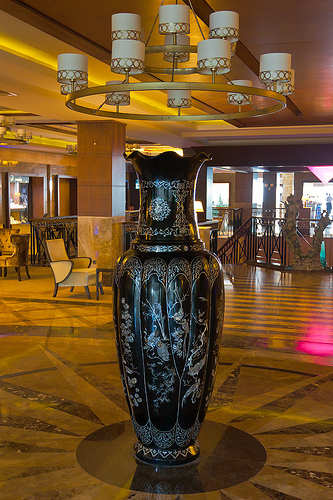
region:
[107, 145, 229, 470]
a large black vase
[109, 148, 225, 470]
the vase has flowers on it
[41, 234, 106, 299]
a cream colored chair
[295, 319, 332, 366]
a pink reflection on the floor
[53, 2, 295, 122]
a large golden chandelier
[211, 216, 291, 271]
the railing is black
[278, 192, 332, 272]
a sculpture in front of the railing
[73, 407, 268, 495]
a brown circle on the floor around the vase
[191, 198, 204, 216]
the lamp is lit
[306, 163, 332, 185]
a pink triangular light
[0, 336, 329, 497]
Flooring with a star design.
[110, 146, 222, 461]
A tall decorative vase.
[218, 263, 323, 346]
Brown striped flooring.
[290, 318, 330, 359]
Pink light reflecting off of the floor.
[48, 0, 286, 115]
A chandelier hanging from the ceiling.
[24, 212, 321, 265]
Black metal railing.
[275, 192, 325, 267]
Statue shaped like a tree trunk.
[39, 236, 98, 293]
Tan chair with a brown frame.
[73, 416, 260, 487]
A brown circle on the flooring.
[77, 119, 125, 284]
A brown and tan beam.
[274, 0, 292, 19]
part of a ceiling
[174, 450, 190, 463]
edge of a vase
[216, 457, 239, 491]
part of a surface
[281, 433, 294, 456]
part of a surface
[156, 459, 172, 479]
base of a vase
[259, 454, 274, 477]
[part pfo a line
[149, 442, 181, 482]
edge of a vase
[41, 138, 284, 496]
a giant vase on the floor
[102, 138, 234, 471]
a Chinese vase on floor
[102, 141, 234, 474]
black vase with white motives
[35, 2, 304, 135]
a ceiling lamp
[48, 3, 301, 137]
ceiling lamp has two circles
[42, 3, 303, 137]
lights around ceiling lamd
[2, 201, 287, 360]
two chairs in a waiting room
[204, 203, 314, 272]
black rails in front a building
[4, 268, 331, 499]
floor is color yellow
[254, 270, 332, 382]
a pink reflection on floor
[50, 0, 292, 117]
a large circular chandelier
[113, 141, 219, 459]
a black and white vase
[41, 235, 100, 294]
a white chair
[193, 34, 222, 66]
a small white light shade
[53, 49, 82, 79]
a small white light shade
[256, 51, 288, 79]
a small white light shade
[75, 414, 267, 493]
circular design on the floor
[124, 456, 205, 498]
reflection of a vase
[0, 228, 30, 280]
two chairs in the distance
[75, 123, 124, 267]
a stone and wooden pillar